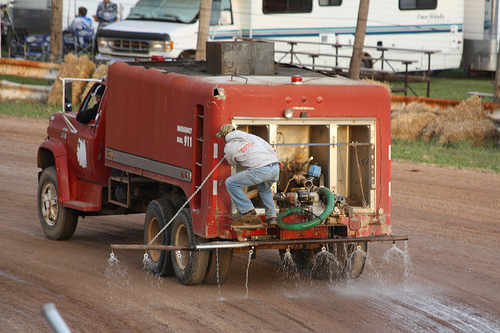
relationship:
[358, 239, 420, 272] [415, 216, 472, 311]
water spraying on dirt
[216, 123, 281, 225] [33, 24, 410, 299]
man on back of a truck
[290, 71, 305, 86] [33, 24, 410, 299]
light on top of a truck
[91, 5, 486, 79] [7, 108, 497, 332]
rv near race track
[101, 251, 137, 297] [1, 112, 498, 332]
water sprinkled on road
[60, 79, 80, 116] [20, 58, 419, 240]
mirror attached to truck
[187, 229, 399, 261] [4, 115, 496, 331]
watering system hanging from truck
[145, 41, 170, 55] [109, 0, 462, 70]
headlight in front of camper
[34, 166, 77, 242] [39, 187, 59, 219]
tire on metal rim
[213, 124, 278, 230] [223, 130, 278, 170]
man wearing a hoodie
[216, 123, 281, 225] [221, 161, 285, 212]
man wearing jeans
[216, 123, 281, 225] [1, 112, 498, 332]
man water road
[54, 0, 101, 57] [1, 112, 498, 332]
man water road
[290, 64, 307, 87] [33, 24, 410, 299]
indicator on truck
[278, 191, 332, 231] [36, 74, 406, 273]
hose on truck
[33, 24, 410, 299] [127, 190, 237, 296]
truck has wheels